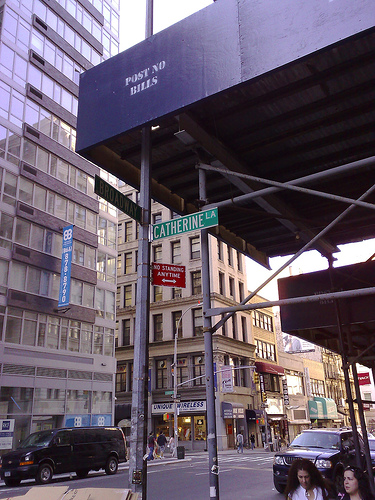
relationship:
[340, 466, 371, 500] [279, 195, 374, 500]
couple walking on sidewalk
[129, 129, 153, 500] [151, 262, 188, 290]
pole with a sign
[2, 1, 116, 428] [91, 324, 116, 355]
building has windows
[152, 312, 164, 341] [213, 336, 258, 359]
windows have an overhang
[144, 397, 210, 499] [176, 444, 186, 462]
street corner has a trash can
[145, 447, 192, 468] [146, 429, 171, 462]
sidewalk has pedestrians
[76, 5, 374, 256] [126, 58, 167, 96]
overhag has stenciled writting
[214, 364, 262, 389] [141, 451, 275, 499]
traffic light over street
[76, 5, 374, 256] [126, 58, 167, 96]
awning has writting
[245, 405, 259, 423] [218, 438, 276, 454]
awning over sidewalk